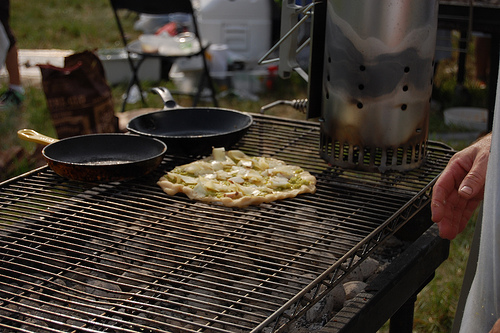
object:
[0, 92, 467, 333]
grill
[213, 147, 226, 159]
chicken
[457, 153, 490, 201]
thumb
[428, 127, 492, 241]
right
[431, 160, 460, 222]
finger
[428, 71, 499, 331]
person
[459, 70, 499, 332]
shirt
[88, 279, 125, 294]
charcoal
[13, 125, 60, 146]
handle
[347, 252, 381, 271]
coals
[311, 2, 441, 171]
furnace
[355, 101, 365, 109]
marks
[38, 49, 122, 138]
bag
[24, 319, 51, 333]
coal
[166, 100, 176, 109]
black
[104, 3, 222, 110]
chair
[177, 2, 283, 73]
cooler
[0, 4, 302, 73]
distance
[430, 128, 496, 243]
hand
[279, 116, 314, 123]
metal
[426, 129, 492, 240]
man's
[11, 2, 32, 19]
grass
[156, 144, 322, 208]
food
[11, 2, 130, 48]
back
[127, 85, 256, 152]
light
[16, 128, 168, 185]
dish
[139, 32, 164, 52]
containers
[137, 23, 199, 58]
stuff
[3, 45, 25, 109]
leg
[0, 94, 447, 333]
grate